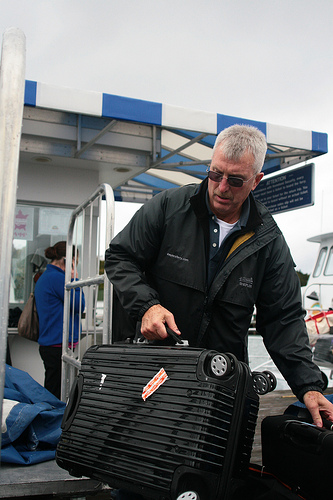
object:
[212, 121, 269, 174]
hair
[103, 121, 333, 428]
man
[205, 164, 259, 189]
sunglasses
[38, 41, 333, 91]
sky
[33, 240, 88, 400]
woman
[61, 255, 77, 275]
phone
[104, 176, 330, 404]
windbreaker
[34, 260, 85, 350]
jacket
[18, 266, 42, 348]
bag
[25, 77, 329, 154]
roof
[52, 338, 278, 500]
suitcase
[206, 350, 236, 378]
wheels